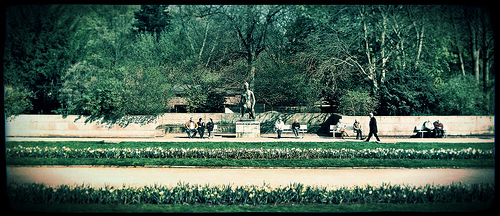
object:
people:
[184, 113, 444, 143]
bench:
[204, 124, 447, 138]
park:
[3, 5, 495, 213]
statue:
[237, 82, 257, 120]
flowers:
[11, 145, 494, 160]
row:
[9, 138, 497, 209]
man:
[364, 112, 381, 142]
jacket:
[369, 117, 378, 131]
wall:
[1, 113, 498, 136]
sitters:
[422, 119, 448, 139]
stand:
[236, 122, 261, 139]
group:
[17, 145, 241, 205]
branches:
[305, 10, 438, 100]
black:
[371, 122, 378, 132]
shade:
[97, 112, 162, 128]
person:
[274, 117, 285, 139]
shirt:
[275, 121, 284, 130]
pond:
[21, 162, 487, 193]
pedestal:
[235, 121, 261, 138]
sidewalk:
[11, 134, 490, 143]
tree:
[0, 5, 494, 115]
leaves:
[373, 60, 452, 109]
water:
[47, 168, 462, 192]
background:
[16, 39, 476, 136]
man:
[353, 118, 365, 140]